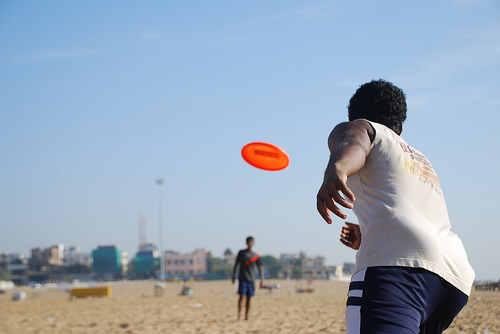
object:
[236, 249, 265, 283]
grey shirt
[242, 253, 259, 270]
red strip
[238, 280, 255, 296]
blue shorts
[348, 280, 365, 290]
stripe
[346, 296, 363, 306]
stripe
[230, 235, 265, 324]
boy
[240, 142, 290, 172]
frisbee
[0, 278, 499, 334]
beach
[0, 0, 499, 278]
sky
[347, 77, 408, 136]
hair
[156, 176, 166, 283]
pole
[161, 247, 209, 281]
building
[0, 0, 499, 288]
distance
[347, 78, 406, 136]
head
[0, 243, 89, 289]
building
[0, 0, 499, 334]
back ground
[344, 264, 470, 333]
shorts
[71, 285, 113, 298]
box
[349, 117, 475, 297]
grey shirt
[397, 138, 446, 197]
letters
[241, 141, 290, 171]
freezbee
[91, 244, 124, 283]
blue building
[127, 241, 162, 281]
blue building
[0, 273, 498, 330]
sand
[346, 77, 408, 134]
back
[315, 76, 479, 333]
man